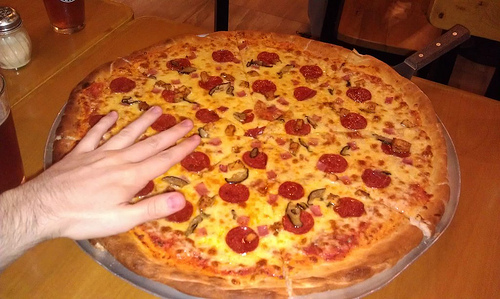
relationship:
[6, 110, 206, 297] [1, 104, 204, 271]
arm on man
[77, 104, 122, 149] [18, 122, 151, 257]
pinky on man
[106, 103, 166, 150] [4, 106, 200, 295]
ring finger on man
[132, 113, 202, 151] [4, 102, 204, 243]
middle finger on man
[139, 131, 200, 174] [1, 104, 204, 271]
index finger on man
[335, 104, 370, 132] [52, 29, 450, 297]
pepperoni topping pizza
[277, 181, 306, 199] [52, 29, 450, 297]
pepperoni topping pizza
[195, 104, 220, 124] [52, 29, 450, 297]
pepperoni topping pizza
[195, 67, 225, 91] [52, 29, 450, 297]
pepperoni topping pizza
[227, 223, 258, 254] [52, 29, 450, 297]
pepperoni topping pizza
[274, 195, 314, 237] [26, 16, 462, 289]
pepperoni topping pizza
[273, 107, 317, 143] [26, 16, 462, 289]
pepperoni topping pizza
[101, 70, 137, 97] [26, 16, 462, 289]
pepperoni topping pizza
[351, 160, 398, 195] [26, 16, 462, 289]
pepperoni topping pizza